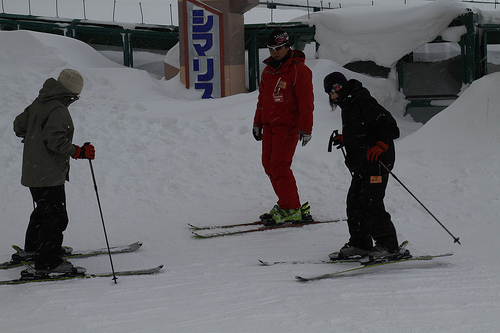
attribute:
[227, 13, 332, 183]
man — wearing, hold, black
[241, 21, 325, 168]
person — wearing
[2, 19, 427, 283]
people — ski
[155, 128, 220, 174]
ski — green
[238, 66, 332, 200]
suit — red, snow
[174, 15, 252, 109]
sign — background, blue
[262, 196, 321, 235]
boot — ski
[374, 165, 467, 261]
pole — ski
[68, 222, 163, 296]
ski — gre, glove, pair, pole, black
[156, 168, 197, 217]
snow — white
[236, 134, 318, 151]
glove — grey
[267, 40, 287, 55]
sun — glass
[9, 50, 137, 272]
skier — wearing, holding, black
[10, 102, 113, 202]
jacket — ski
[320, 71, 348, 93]
cap — stocking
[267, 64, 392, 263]
woman — wearing